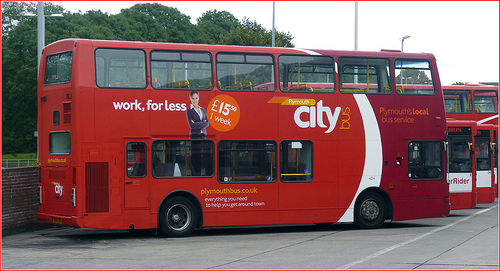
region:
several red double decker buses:
[42, 33, 498, 237]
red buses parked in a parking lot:
[46, 53, 496, 237]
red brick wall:
[6, 158, 35, 228]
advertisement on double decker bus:
[105, 89, 351, 141]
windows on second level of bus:
[91, 54, 424, 96]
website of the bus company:
[190, 178, 270, 198]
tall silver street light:
[27, 0, 53, 100]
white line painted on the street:
[334, 216, 484, 269]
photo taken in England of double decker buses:
[12, 20, 482, 259]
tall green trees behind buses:
[9, 1, 305, 147]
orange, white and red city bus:
[36, 36, 453, 238]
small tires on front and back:
[158, 186, 395, 236]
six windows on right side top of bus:
[91, 46, 439, 96]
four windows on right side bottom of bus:
[117, 137, 317, 186]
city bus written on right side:
[292, 99, 351, 136]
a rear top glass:
[40, 48, 76, 89]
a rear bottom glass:
[47, 129, 76, 158]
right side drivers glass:
[406, 137, 446, 183]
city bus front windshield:
[443, 139, 453, 184]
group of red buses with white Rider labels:
[253, 80, 498, 210]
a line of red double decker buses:
[31, 26, 498, 238]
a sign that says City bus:
[285, 94, 353, 133]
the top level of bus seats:
[40, 40, 443, 118]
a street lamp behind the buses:
[398, 33, 410, 48]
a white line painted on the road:
[331, 201, 496, 269]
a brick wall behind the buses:
[1, 167, 47, 230]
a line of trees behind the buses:
[0, 0, 295, 150]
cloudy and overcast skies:
[58, 1, 498, 86]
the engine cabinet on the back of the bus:
[36, 148, 121, 225]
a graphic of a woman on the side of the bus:
[188, 90, 209, 135]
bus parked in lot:
[35, 46, 445, 227]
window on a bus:
[90, 40, 145, 100]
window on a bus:
[145, 46, 215, 91]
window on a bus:
[215, 45, 275, 90]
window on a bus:
[272, 50, 337, 100]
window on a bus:
[335, 50, 400, 95]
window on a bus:
[390, 45, 435, 95]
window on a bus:
[280, 130, 316, 200]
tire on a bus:
[350, 182, 405, 227]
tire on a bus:
[152, 179, 197, 233]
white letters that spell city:
[296, 100, 341, 152]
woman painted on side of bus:
[152, 77, 215, 175]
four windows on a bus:
[106, 127, 326, 207]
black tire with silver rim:
[166, 195, 211, 240]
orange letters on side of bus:
[373, 105, 441, 134]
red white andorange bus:
[133, 47, 450, 258]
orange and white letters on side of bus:
[195, 180, 273, 219]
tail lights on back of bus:
[33, 183, 89, 221]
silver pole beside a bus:
[2, 7, 62, 124]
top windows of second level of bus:
[34, 44, 430, 96]